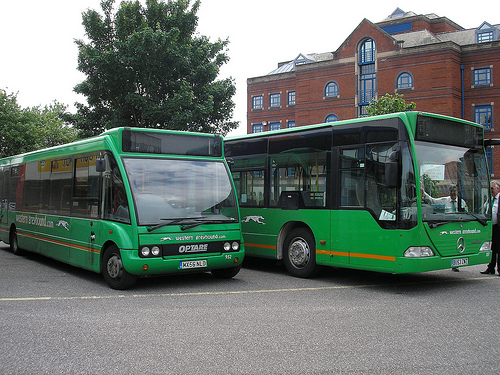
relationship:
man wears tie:
[482, 173, 499, 277] [479, 197, 498, 221]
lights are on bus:
[137, 235, 242, 260] [0, 118, 253, 293]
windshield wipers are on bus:
[143, 211, 239, 239] [0, 118, 253, 293]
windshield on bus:
[117, 152, 242, 231] [0, 118, 253, 293]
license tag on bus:
[175, 258, 210, 272] [0, 118, 253, 293]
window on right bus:
[399, 132, 490, 223] [215, 107, 495, 289]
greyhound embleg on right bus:
[240, 210, 272, 229] [215, 107, 495, 289]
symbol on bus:
[11, 211, 73, 232] [0, 118, 253, 293]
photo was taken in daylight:
[3, 4, 500, 371] [4, 1, 361, 90]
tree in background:
[56, 0, 246, 138] [2, 8, 498, 136]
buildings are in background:
[234, 12, 495, 126] [2, 8, 498, 136]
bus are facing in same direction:
[0, 126, 246, 290] [464, 30, 491, 325]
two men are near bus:
[411, 176, 499, 279] [0, 126, 246, 290]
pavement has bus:
[4, 285, 497, 371] [0, 126, 246, 290]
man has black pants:
[482, 173, 499, 277] [481, 219, 500, 274]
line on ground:
[1, 274, 497, 301] [5, 306, 490, 370]